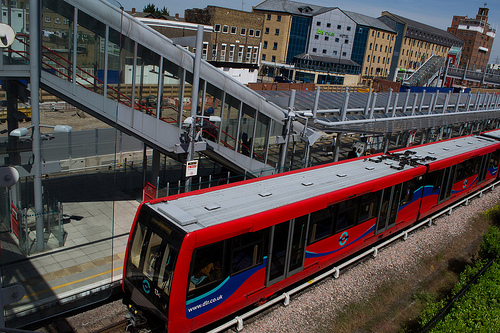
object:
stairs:
[5, 5, 317, 192]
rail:
[199, 182, 500, 333]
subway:
[117, 115, 495, 326]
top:
[143, 129, 498, 239]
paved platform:
[16, 119, 496, 321]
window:
[133, 215, 176, 292]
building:
[251, 0, 398, 88]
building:
[379, 6, 452, 91]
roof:
[143, 126, 499, 232]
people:
[199, 106, 217, 139]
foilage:
[421, 278, 500, 332]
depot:
[3, 0, 500, 328]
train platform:
[240, 78, 498, 119]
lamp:
[10, 20, 71, 255]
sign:
[184, 159, 200, 177]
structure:
[5, 0, 499, 174]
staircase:
[30, 1, 284, 179]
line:
[21, 265, 123, 300]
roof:
[342, 9, 395, 35]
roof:
[396, 15, 455, 40]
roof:
[255, 0, 325, 21]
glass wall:
[1, 1, 113, 324]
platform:
[1, 186, 151, 303]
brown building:
[185, 6, 257, 61]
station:
[20, 11, 482, 327]